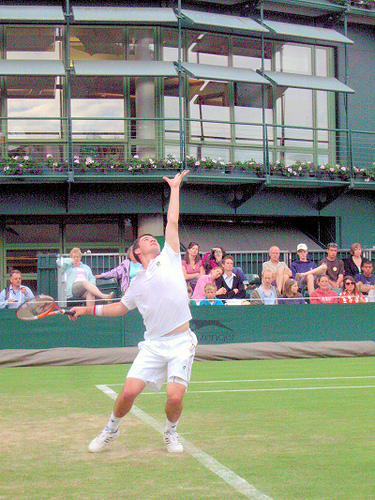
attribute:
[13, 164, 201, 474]
tennis player — man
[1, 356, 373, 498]
court — grass, green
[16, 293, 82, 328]
racket — red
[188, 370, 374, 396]
lines — white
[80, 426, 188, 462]
shoes — white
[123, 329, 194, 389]
shorts — white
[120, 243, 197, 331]
shirt — white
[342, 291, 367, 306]
shirt — plaid, red/white